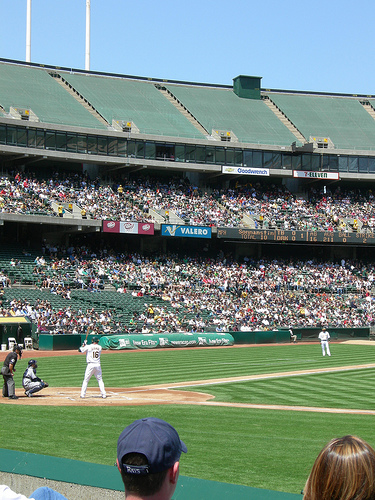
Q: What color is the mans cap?
A: Blue.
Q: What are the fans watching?
A: Baseball game.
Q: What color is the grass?
A: Green.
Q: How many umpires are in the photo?
A: One.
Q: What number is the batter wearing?
A: 16.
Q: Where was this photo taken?
A: Baseball field.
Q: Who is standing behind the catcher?
A: Umpire.